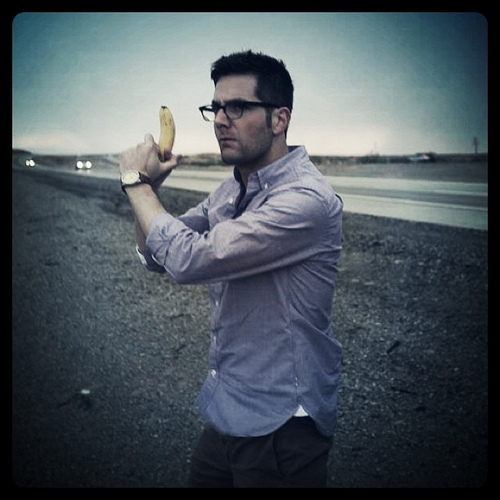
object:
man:
[125, 68, 341, 487]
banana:
[157, 103, 178, 163]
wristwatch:
[119, 167, 154, 188]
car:
[402, 151, 439, 164]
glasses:
[198, 99, 274, 122]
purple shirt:
[136, 145, 344, 442]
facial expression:
[201, 75, 263, 166]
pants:
[187, 410, 328, 499]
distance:
[13, 110, 188, 226]